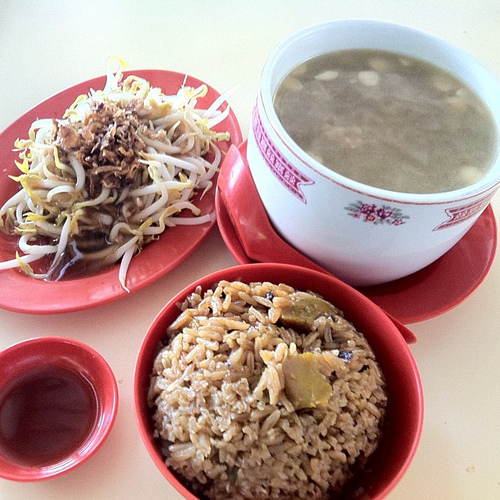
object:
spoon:
[215, 143, 429, 348]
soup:
[279, 34, 499, 195]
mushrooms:
[356, 65, 379, 90]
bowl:
[251, 10, 498, 208]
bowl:
[128, 258, 428, 498]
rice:
[216, 389, 225, 399]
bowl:
[1, 335, 123, 487]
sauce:
[63, 408, 75, 423]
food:
[0, 3, 498, 490]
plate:
[1, 55, 254, 318]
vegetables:
[146, 188, 172, 215]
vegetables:
[287, 294, 323, 321]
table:
[1, 10, 497, 497]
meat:
[75, 107, 134, 169]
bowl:
[216, 87, 499, 343]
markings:
[428, 186, 497, 230]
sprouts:
[58, 223, 69, 266]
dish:
[210, 125, 494, 323]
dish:
[0, 333, 119, 484]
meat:
[274, 348, 330, 407]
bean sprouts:
[117, 249, 134, 293]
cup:
[1, 327, 119, 485]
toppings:
[74, 113, 115, 155]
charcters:
[251, 97, 315, 205]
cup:
[257, 19, 495, 278]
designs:
[343, 195, 410, 231]